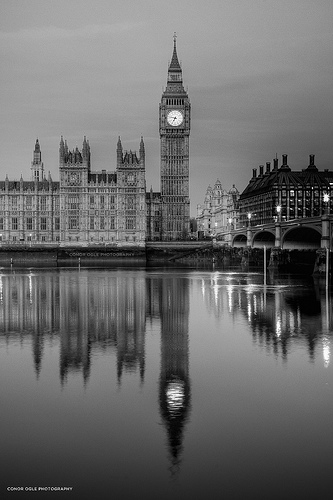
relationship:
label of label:
[5, 484, 73, 492] [5, 484, 73, 492]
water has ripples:
[1, 267, 333, 499] [248, 337, 327, 363]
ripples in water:
[248, 337, 327, 363] [1, 267, 333, 499]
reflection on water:
[2, 274, 191, 466] [1, 267, 333, 499]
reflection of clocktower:
[2, 274, 191, 466] [159, 32, 193, 241]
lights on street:
[214, 193, 330, 228] [2, 242, 211, 245]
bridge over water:
[203, 212, 332, 251] [1, 267, 333, 499]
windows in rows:
[240, 188, 333, 226] [240, 172, 330, 225]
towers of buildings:
[58, 138, 146, 189] [2, 137, 148, 251]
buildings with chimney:
[2, 137, 148, 251] [252, 154, 320, 179]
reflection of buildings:
[2, 274, 191, 466] [2, 137, 148, 251]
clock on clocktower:
[166, 109, 184, 127] [159, 32, 193, 241]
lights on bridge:
[214, 193, 330, 228] [203, 212, 332, 251]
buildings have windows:
[2, 137, 148, 251] [5, 196, 139, 237]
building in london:
[197, 182, 242, 244] [1, 1, 332, 499]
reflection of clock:
[2, 274, 191, 466] [166, 109, 184, 127]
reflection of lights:
[2, 274, 191, 466] [214, 193, 330, 228]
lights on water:
[214, 193, 330, 228] [1, 267, 333, 499]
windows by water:
[240, 188, 333, 226] [1, 267, 333, 499]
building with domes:
[197, 182, 242, 244] [207, 176, 239, 194]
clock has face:
[166, 109, 184, 127] [170, 113, 180, 123]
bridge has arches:
[203, 212, 332, 251] [231, 232, 277, 248]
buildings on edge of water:
[2, 137, 148, 251] [1, 267, 333, 499]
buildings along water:
[2, 137, 148, 251] [1, 267, 333, 499]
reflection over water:
[2, 274, 191, 466] [1, 267, 333, 499]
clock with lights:
[166, 109, 184, 127] [214, 193, 330, 228]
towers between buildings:
[58, 138, 146, 189] [2, 137, 148, 251]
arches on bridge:
[231, 232, 277, 248] [203, 212, 332, 251]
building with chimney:
[197, 182, 242, 244] [252, 154, 320, 179]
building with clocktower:
[197, 182, 242, 244] [159, 32, 192, 240]